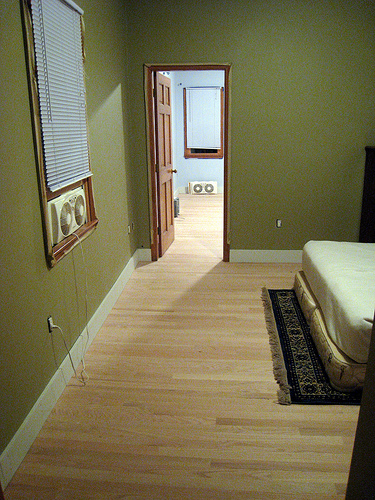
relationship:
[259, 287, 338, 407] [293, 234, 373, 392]
rug under bed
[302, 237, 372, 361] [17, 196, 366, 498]
mattress on floor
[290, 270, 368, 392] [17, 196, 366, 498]
boxspring on floor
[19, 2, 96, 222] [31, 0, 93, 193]
window on blinds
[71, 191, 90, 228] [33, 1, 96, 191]
electric fan mounted on window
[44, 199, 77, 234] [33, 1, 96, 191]
electric fan mounted on window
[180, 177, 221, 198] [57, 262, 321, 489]
fan on floor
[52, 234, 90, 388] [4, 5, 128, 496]
cord plugged into wall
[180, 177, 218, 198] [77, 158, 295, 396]
fan on floor